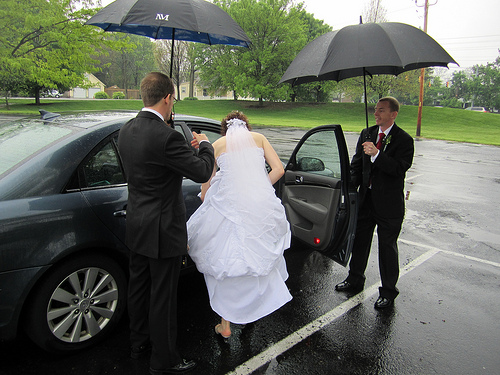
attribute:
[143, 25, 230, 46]
clouds — printed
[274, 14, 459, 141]
umbrella — black, plain, wet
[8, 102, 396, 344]
car — gray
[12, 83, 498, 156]
area — large, grassy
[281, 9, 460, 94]
umbrella — black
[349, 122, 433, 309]
suit — black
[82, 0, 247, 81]
umbrella — black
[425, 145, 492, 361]
parking lot — slick, wet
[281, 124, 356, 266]
door — open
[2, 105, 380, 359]
car — black, parked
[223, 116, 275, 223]
veil — white, clear, wedding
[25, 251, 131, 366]
wheel — rear, white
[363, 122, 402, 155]
shirt — white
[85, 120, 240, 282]
suit — black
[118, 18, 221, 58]
sky — white and blue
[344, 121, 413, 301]
suit — black